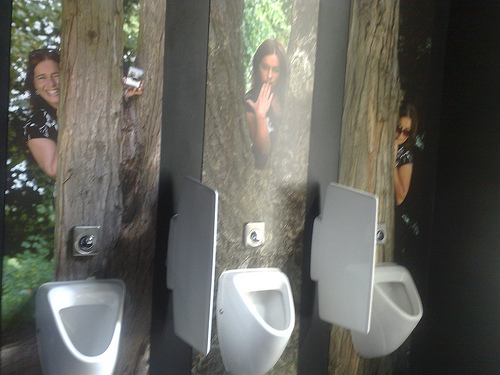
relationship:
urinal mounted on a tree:
[34, 279, 126, 374] [58, 2, 155, 274]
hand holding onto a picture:
[122, 78, 144, 102] [126, 64, 145, 90]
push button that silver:
[83, 235, 96, 247] [84, 234, 95, 247]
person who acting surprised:
[241, 38, 290, 171] [256, 51, 285, 91]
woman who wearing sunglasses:
[390, 103, 418, 205] [395, 126, 412, 138]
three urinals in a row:
[35, 259, 423, 373] [36, 263, 423, 372]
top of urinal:
[36, 275, 127, 308] [34, 279, 126, 374]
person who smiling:
[22, 48, 61, 181] [45, 87, 60, 97]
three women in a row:
[23, 40, 418, 207] [21, 38, 419, 207]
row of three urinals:
[36, 263, 423, 372] [35, 259, 423, 373]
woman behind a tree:
[390, 103, 418, 205] [351, 2, 397, 202]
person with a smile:
[22, 48, 61, 181] [45, 87, 60, 97]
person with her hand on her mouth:
[241, 38, 290, 171] [245, 78, 274, 113]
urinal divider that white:
[166, 176, 219, 352] [183, 284, 203, 328]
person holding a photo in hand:
[22, 48, 61, 181] [122, 78, 144, 102]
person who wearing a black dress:
[22, 48, 61, 181] [20, 100, 61, 147]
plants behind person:
[1, 0, 63, 349] [22, 48, 61, 181]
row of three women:
[21, 38, 419, 207] [23, 40, 418, 207]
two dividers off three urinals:
[164, 178, 380, 355] [35, 259, 423, 373]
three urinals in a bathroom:
[35, 259, 423, 373] [0, 0, 499, 375]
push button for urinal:
[83, 235, 96, 247] [34, 279, 126, 374]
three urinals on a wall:
[35, 259, 423, 373] [0, 0, 447, 373]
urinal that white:
[34, 279, 126, 374] [95, 357, 111, 368]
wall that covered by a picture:
[0, 0, 447, 373] [2, 0, 453, 375]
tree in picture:
[58, 2, 155, 274] [2, 0, 453, 375]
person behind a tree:
[241, 38, 290, 171] [211, 0, 266, 256]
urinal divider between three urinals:
[166, 176, 219, 352] [35, 259, 423, 373]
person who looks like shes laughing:
[241, 38, 290, 171] [256, 53, 283, 92]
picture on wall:
[2, 0, 453, 375] [0, 0, 447, 373]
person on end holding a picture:
[22, 48, 61, 181] [126, 64, 145, 90]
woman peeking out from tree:
[390, 103, 418, 205] [351, 2, 397, 202]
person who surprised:
[241, 38, 290, 171] [256, 51, 285, 91]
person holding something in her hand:
[22, 48, 61, 181] [122, 78, 144, 102]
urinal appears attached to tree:
[34, 279, 126, 374] [58, 2, 155, 274]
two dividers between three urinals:
[164, 178, 380, 355] [35, 259, 423, 373]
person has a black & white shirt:
[22, 48, 61, 181] [20, 100, 61, 147]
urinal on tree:
[34, 279, 126, 374] [58, 2, 155, 274]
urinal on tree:
[217, 267, 294, 374] [211, 0, 266, 256]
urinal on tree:
[370, 265, 422, 360] [351, 2, 397, 202]